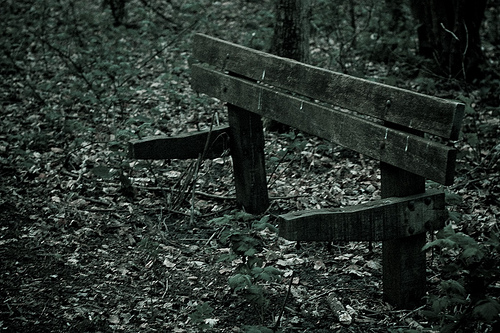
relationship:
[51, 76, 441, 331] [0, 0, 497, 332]
branches on ground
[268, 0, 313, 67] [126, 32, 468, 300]
trunk behind bench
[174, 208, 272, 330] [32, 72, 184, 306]
leaves on ground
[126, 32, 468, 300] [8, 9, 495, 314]
bench by woods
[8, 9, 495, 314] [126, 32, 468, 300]
woods has a bench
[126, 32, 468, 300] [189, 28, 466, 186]
bench has seat back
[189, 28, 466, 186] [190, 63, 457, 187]
seat back has slat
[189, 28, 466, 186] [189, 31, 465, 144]
seat back has slat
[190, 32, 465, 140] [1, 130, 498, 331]
slats on ground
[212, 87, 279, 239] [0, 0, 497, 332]
pole above ground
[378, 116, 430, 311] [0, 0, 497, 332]
pole above ground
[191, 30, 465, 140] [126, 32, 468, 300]
slats on back of bench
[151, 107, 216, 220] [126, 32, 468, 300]
stick leaning against bench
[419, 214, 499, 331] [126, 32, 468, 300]
plant next to bench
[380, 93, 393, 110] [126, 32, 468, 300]
lag bolt on bench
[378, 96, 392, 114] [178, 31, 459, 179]
bolts in wood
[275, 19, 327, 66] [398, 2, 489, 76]
bark on tree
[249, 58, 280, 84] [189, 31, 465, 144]
mark soiling slat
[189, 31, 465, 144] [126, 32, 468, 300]
slat mounted on bench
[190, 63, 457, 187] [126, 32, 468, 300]
slat mounted on bench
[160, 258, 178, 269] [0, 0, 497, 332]
leaf lying on ground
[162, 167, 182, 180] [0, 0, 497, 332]
leaf lying on ground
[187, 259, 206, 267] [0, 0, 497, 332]
leaf lying on ground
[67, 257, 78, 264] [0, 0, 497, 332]
leaf lying on ground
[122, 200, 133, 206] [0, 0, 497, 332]
leaf lying on ground